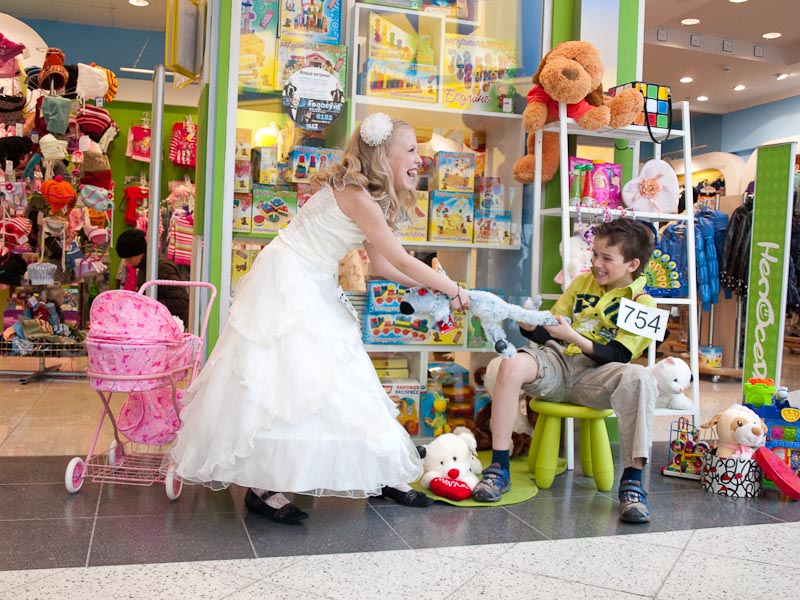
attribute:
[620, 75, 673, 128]
toy — on white shelf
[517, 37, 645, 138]
toy — on white shelf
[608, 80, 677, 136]
toy — on white shelf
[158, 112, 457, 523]
young girl — in white dress, holding a stuffed animal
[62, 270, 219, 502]
baby carriage — pink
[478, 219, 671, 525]
boy — in green shirt, sitting on chair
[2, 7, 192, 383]
clothing store — inside mall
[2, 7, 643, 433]
baby clothes/toys — store in mall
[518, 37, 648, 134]
stuffed bear — big, tan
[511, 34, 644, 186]
stuffed bear — tan, big, sitting up high on shelf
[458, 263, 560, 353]
animal — stuffed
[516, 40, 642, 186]
dog — stuffed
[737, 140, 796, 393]
sign — green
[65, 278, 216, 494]
toy stroller — pink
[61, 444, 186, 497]
wheels — white and pink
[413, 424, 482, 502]
stuffed animal — white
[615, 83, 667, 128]
rubik cube — large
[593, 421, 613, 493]
leg — one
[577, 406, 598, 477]
leg — one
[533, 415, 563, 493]
leg — one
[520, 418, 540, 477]
leg — one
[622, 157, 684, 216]
box — white, heart shaped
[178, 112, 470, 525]
girl — young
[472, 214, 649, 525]
boy — sitting down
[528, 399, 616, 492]
stool — yellow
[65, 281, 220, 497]
stroller — white and pink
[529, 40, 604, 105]
dog — stuffed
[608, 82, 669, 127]
cube — large, rubicks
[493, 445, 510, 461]
sock — blue